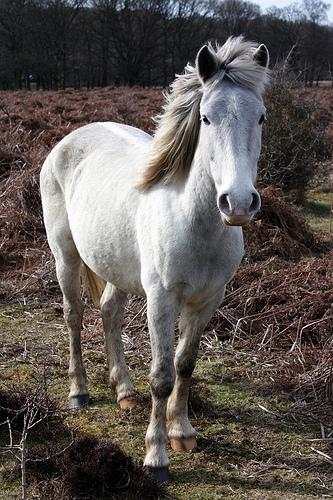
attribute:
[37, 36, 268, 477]
horse — fury, white color, tan, standing, white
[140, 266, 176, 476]
leg — strong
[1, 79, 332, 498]
grass — heaped, brown, hay, dry, straw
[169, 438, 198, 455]
hoof — tan, orange, black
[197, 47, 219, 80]
ear — black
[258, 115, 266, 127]
eye — open, black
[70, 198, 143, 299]
belly — fat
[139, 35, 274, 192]
mane — blowing, white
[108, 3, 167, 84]
tree — leafless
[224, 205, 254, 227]
nose — white, wide, stained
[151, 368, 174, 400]
knee — dirty, dark